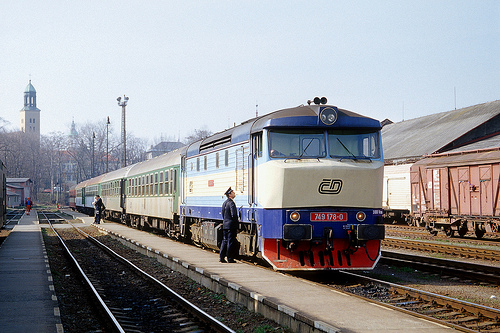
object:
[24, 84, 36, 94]
dome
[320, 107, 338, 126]
light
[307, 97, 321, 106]
horn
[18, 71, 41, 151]
building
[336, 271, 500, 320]
tracks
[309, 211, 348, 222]
tag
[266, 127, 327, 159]
windows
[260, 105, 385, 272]
train front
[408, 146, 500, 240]
train car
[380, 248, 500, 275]
tracks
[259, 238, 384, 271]
red part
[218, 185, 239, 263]
man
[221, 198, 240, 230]
jacket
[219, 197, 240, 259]
clothes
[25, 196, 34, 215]
person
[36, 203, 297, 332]
railroad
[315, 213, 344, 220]
lettering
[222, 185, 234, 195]
cap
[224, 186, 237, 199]
head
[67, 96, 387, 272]
train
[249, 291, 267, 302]
white stripes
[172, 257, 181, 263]
white stripes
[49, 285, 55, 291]
white stripes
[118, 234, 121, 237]
white stripes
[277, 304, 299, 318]
white stripes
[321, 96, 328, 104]
horns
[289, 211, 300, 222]
headlight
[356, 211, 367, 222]
headlight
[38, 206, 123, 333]
track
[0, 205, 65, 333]
sidewalk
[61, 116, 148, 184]
tree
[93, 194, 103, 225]
employee